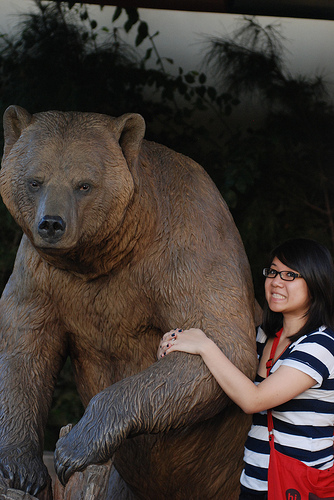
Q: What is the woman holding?
A: A bear statue.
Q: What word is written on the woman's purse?
A: "hi".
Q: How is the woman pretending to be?
A: Scared.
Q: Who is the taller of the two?
A: The bear.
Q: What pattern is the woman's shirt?
A: Blue and white stripes.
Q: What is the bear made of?
A: Plastic.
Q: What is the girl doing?
A: Posing.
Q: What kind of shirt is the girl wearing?
A: Short sleeve shirt.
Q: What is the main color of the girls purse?
A: Red.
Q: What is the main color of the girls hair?
A: Black.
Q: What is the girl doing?
A: Smiling.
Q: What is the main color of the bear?
A: Brown.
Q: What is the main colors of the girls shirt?
A: Blue and white.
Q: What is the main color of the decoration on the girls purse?
A: Black.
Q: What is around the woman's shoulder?
A: A bag.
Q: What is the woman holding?
A: A bear.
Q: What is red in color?
A: Woman's bag.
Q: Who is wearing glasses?
A: The woman.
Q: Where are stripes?
A: On woman's shirt.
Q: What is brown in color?
A: The bear.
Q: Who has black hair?
A: A woman.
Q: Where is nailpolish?
A: On woman's nails.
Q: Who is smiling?
A: Woman in striped shirt.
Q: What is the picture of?
A: A girl and a bear statue.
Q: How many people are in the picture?
A: One.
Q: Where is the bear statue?
A: On the left.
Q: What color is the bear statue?
A: Brown.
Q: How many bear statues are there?
A: One.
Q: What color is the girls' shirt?
A: Blue and white.